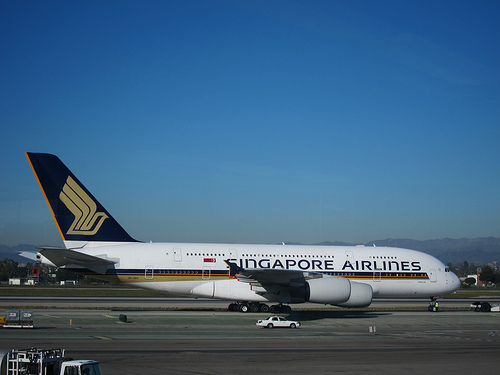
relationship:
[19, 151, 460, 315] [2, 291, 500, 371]
plane on runway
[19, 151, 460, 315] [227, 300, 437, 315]
plane has wheels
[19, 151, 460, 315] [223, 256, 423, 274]
plane has writing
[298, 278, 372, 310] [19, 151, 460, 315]
engines on a plane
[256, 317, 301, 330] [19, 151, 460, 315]
car near plane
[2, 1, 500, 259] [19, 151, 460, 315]
sky behind plane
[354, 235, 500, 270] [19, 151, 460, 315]
mountains are behind plane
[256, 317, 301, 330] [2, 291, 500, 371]
car on runway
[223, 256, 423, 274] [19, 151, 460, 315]
writing on side of plane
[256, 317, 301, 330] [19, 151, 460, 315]
car next to plane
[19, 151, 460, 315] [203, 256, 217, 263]
plane has red sign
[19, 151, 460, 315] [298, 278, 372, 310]
plane has two engines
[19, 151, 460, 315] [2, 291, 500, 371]
plane parked on runway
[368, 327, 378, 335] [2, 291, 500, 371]
object on runway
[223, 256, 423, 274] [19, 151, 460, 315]
writing on plane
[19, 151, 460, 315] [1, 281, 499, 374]
plane on ground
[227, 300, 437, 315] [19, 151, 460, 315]
wheels are on front of plane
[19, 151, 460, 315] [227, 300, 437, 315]
plane has rear wheels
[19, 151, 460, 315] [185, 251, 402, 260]
plane has windows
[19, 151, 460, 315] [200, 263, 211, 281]
plane has a door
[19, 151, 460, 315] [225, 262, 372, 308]
plane has wing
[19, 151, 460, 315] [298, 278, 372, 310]
plane has engines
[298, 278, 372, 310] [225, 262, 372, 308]
engines are on wing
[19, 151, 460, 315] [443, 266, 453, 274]
plane has cockpit windows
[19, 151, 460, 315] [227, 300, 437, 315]
plane has front wheels